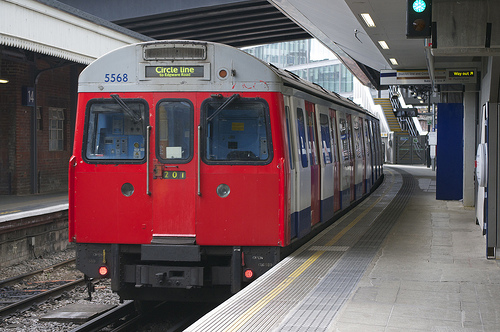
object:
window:
[319, 111, 336, 163]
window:
[339, 115, 350, 158]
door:
[150, 91, 198, 247]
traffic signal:
[405, 0, 438, 37]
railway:
[0, 254, 158, 332]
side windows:
[294, 107, 307, 167]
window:
[338, 116, 350, 166]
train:
[62, 37, 383, 300]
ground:
[414, 165, 436, 198]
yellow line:
[222, 192, 382, 329]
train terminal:
[0, 0, 499, 332]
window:
[82, 94, 154, 164]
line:
[0, 221, 153, 329]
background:
[233, 44, 380, 101]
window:
[48, 106, 67, 151]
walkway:
[180, 162, 497, 332]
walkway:
[0, 189, 67, 222]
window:
[294, 102, 310, 169]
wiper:
[194, 90, 243, 132]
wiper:
[108, 93, 147, 129]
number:
[23, 87, 35, 107]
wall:
[11, 63, 71, 205]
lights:
[217, 68, 230, 78]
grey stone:
[182, 162, 500, 332]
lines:
[222, 250, 326, 330]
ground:
[327, 258, 498, 318]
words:
[153, 65, 196, 76]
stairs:
[372, 97, 429, 164]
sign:
[450, 70, 476, 78]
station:
[0, 0, 499, 332]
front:
[64, 37, 299, 307]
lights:
[357, 8, 398, 70]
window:
[153, 95, 195, 167]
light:
[406, 0, 432, 37]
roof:
[267, 1, 497, 103]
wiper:
[108, 93, 147, 123]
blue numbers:
[103, 72, 129, 82]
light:
[99, 266, 109, 277]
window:
[199, 91, 274, 167]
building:
[0, 0, 169, 215]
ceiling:
[269, 0, 496, 97]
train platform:
[178, 160, 497, 332]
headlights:
[119, 182, 135, 197]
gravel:
[3, 240, 189, 332]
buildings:
[233, 38, 436, 165]